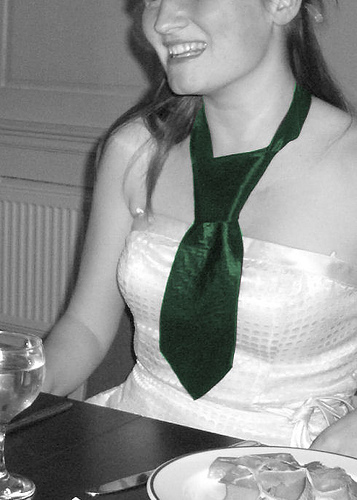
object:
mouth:
[167, 39, 207, 65]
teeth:
[169, 42, 206, 58]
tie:
[158, 78, 312, 402]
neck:
[201, 34, 298, 156]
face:
[136, 0, 277, 102]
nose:
[153, 1, 185, 36]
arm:
[30, 124, 133, 395]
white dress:
[80, 209, 355, 451]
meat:
[210, 451, 357, 500]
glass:
[0, 327, 45, 500]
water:
[1, 359, 45, 425]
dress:
[83, 205, 354, 447]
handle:
[226, 439, 261, 446]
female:
[36, 0, 356, 457]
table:
[2, 387, 354, 498]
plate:
[146, 444, 355, 500]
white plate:
[147, 445, 356, 500]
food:
[207, 453, 357, 499]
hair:
[93, 0, 355, 228]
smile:
[162, 39, 207, 65]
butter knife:
[72, 466, 156, 500]